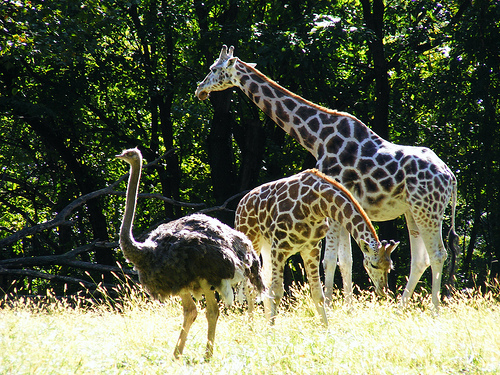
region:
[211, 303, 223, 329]
leg of an ostrich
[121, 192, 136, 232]
neck of an ostrich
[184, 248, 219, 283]
feathers of an ostrich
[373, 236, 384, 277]
head of a giraffe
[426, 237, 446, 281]
back leg of a giraffe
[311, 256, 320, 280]
front leg of a giraffe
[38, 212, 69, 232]
branch of a tree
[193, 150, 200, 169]
leaves of a tree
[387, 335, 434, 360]
edges of a grass plantation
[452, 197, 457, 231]
tail of a giraffe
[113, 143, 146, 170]
the head of an ostrich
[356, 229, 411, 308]
the head of a giraffe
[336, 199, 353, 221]
a spot on the giraffe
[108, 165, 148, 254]
the neck of an ostrich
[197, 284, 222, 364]
the leg of an ostrich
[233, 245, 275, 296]
the tail of an ostrich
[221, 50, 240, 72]
the ear of a giraffe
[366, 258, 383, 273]
the eye of a giraffe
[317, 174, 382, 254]
the neck of a giraffe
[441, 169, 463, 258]
the tail of a giraffe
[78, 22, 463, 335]
three animals in a field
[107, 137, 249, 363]
ostrich standing in grass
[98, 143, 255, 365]
ostrich with long neck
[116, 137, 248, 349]
ostrich with black feathers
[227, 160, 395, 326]
giraffe leaning down eating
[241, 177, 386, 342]
giraffe with orange and white spots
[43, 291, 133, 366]
patch of grass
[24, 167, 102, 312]
tree that has fallen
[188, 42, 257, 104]
giraffe head with knots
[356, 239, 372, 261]
right giraffe ear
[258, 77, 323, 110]
neck of a giraffe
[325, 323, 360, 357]
part of a grass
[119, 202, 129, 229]
neck of an ostrich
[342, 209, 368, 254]
neck of a giraffe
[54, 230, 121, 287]
part of a tree branches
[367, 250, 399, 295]
head of a giraffe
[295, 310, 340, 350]
part of a grass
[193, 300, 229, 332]
part of a knee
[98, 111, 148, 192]
head of an ostrich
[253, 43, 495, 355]
2 giraffes are pictured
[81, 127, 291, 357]
1 ostrich is pictured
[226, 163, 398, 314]
the giraffe is bending its neck down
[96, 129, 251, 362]
the ostrich is black and white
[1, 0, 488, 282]
many trees are behind the animals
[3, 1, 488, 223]
the tree's leaves are green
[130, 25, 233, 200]
the branches are brown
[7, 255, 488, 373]
the grass is long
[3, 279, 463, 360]
the grass is brown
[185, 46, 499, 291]
the giraffes are brown and orange